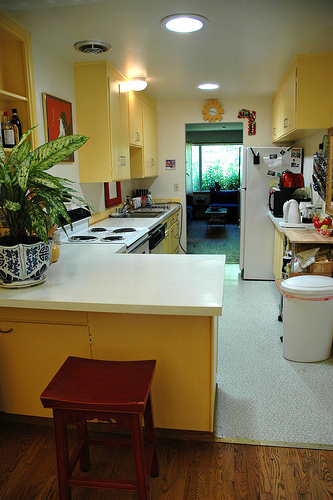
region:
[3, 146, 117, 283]
a plant in a kitchen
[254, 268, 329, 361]
a garbage can in a kitchen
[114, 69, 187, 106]
a light in a kitchen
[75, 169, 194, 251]
a stove in a kitchen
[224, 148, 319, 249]
a refrigerator in a kitchen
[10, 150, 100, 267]
a plant on a countertop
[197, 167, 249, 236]
a couch in a livingroom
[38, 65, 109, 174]
a picture on a wall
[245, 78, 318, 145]
cabinet in a kitchen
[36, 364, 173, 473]
a chair in a kitchen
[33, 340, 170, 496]
A small stool in the foreground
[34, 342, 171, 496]
The stool is made out of wood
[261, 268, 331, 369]
A trash can that is white in color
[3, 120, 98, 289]
A plant in the foreground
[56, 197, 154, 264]
A stove in the background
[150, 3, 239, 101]
Lights on the ceiling are circular shaped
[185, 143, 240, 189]
A window in the background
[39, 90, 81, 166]
A picture frame in the background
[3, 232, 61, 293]
The pot in the foreground is white and blue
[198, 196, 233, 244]
A small table in the background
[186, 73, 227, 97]
The ceiling light is round.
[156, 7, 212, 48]
The ceiling light is round.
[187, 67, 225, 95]
The ceiling light is on.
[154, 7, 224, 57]
The ceiling light is on.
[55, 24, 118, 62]
The fan cover is silver.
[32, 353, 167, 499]
The stool is wood.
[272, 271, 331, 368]
The trash can is white.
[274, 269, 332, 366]
The trash can has a lid on it.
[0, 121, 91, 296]
The potted plant is leafy.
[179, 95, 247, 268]
The clock is hanging above the doorway.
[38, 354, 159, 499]
Brown wood bar stool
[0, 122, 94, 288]
Green plant in white and blue flower pot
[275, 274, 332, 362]
White trash can with white lid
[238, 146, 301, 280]
White refrigerator with pictures and magnets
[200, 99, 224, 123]
Orange yellow wall clock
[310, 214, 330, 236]
Apples and bananas in a bowl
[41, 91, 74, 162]
Picture in a gold frame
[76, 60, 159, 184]
Yellow cabinets with silver handles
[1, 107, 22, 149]
Two bottles with lids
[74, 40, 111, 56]
Silver ceiling round stove vent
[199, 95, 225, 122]
A yellow flower clock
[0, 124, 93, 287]
A potted plant on a table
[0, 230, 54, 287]
A blue/white pot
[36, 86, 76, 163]
A red painting/picture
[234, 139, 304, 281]
A large white refrigerator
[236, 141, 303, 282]
A refrigerator with lots of pictures on it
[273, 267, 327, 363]
A small white trashcan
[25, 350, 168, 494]
A wooden chair/stool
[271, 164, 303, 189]
A red coffee maker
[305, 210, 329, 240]
A small basket of tomatoes